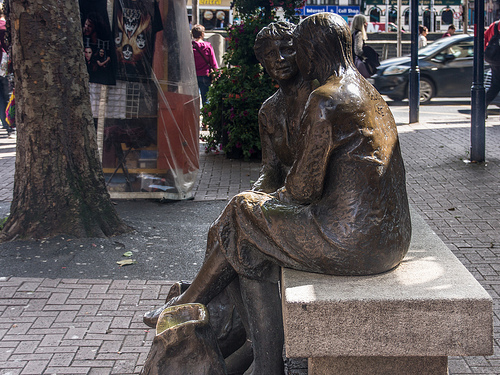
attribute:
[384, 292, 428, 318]
bench — part, stone, edge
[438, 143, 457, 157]
path — part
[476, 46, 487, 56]
post — part, metal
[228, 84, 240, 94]
bush — part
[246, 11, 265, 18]
stem — part, edge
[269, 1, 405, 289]
man — back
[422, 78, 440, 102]
wheel — part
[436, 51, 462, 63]
mirror — part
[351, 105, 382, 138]
sculpture — part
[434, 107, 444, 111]
road — edge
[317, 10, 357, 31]
sunshine — reflecting, shining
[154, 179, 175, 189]
paper — white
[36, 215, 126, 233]
trunk — large, bottom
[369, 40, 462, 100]
car — blue, black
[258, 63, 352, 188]
statues — sitting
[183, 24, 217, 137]
woman — walking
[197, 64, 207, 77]
shirt — purple, black, red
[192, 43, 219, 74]
purse — crossbody, gray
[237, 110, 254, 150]
flowers — purple